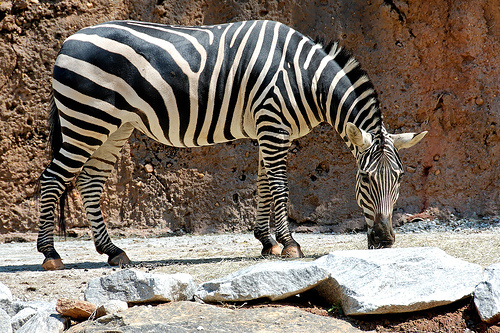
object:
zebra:
[36, 18, 428, 271]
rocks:
[313, 246, 482, 316]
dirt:
[154, 238, 227, 269]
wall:
[2, 0, 500, 241]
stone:
[192, 261, 329, 302]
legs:
[252, 108, 304, 257]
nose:
[372, 225, 396, 244]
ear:
[392, 130, 430, 148]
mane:
[313, 36, 385, 147]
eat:
[366, 231, 396, 249]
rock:
[473, 263, 500, 322]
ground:
[0, 232, 500, 333]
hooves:
[281, 244, 302, 259]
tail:
[34, 91, 73, 239]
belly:
[132, 120, 246, 149]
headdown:
[343, 120, 428, 250]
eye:
[361, 174, 370, 184]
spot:
[110, 22, 201, 73]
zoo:
[0, 0, 500, 333]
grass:
[463, 232, 500, 255]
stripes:
[257, 125, 291, 136]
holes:
[431, 91, 449, 114]